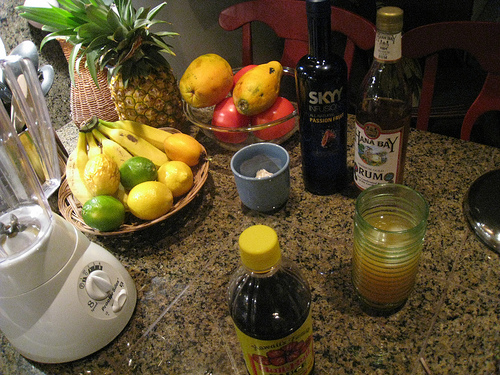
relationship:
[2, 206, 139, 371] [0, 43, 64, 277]
blender has a pitcher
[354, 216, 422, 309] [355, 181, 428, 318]
orange juice in glass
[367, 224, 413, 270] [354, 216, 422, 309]
ice cubes in orange juice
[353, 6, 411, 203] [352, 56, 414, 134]
bottle of rum made of glass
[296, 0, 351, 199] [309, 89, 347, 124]
bottle of vodka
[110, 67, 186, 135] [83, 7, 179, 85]
pineapple has leaves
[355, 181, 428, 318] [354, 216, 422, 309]
glass with orange juice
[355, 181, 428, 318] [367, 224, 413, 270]
glass with ice cubes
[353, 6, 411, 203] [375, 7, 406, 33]
bottle of rum with a cap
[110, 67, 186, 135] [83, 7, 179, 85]
pineapple with leaves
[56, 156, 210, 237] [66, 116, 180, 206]
basket full of bananas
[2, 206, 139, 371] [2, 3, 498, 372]
blender on countertop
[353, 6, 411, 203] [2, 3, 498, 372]
bottle of rum on countertop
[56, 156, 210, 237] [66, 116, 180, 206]
basket with bananas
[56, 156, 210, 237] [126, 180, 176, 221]
basket with lemon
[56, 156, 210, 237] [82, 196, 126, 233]
basket with lime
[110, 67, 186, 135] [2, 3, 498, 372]
pineapple on countertop